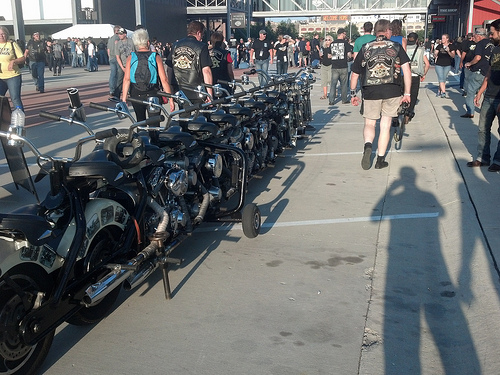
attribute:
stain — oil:
[440, 290, 455, 298]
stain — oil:
[344, 255, 363, 264]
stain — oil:
[264, 257, 281, 268]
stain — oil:
[325, 182, 337, 187]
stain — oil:
[280, 330, 294, 338]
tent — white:
[44, 22, 137, 42]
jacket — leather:
[168, 34, 204, 86]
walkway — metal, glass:
[185, 0, 437, 13]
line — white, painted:
[218, 205, 443, 234]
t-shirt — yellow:
[1, 41, 21, 78]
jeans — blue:
[0, 72, 27, 111]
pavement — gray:
[272, 261, 375, 370]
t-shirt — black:
[433, 40, 453, 65]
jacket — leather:
[169, 40, 202, 89]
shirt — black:
[349, 37, 409, 102]